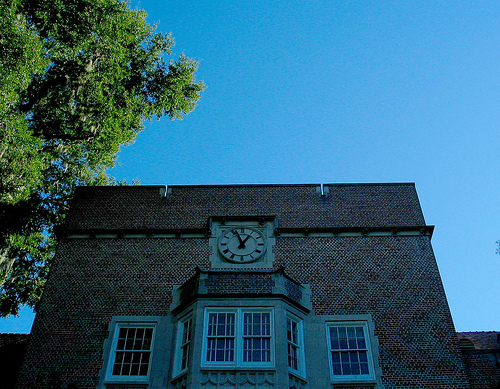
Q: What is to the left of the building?
A: Tree.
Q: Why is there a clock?
A: Tell time.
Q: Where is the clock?
A: On building.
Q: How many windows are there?
A: Six.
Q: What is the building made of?
A: Bricks.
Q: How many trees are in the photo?
A: One.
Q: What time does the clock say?
A: 1:55.